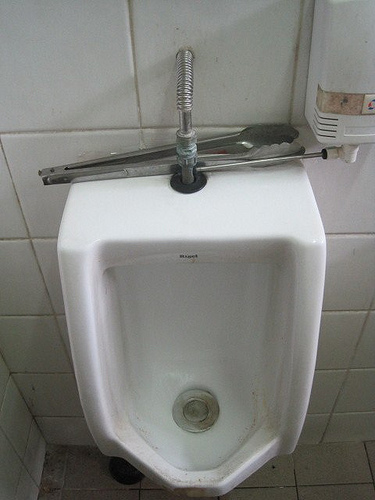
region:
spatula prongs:
[36, 107, 313, 182]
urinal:
[56, 289, 339, 497]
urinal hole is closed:
[159, 367, 239, 446]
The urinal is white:
[47, 315, 156, 466]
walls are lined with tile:
[3, 392, 69, 442]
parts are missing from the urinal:
[135, 55, 246, 196]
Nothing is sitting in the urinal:
[121, 353, 289, 458]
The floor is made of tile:
[317, 458, 366, 496]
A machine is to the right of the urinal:
[302, 9, 374, 197]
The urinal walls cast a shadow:
[126, 218, 302, 447]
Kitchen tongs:
[22, 35, 319, 253]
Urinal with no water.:
[127, 336, 278, 489]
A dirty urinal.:
[125, 346, 283, 491]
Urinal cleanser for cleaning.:
[312, 68, 372, 147]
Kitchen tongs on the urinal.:
[33, 92, 373, 225]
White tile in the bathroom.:
[85, 30, 205, 121]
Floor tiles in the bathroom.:
[45, 437, 120, 492]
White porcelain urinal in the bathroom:
[44, 299, 296, 498]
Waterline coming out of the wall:
[158, 34, 239, 165]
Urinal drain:
[165, 380, 233, 429]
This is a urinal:
[28, 129, 337, 495]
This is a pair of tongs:
[31, 117, 313, 180]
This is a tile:
[2, 125, 163, 252]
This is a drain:
[167, 370, 220, 431]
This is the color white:
[117, 204, 127, 208]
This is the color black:
[182, 185, 186, 190]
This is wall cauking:
[328, 360, 355, 415]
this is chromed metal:
[175, 396, 201, 414]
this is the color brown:
[327, 101, 334, 107]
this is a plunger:
[89, 445, 164, 493]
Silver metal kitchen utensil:
[13, 108, 314, 205]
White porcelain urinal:
[51, 139, 340, 499]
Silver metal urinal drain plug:
[163, 373, 227, 444]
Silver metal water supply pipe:
[167, 37, 201, 191]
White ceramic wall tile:
[120, 0, 304, 136]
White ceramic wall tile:
[316, 231, 373, 322]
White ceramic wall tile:
[0, 310, 67, 384]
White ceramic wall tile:
[13, 358, 82, 438]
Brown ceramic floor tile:
[278, 434, 372, 495]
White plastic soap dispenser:
[298, 0, 374, 168]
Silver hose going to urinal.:
[171, 47, 199, 183]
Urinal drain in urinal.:
[173, 385, 220, 432]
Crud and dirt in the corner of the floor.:
[44, 445, 61, 491]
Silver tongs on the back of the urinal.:
[35, 122, 302, 186]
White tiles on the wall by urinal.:
[322, 358, 370, 439]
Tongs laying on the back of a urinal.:
[38, 120, 304, 185]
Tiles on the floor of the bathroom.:
[301, 444, 372, 498]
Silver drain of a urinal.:
[172, 386, 223, 435]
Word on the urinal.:
[178, 252, 196, 257]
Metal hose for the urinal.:
[174, 46, 199, 184]